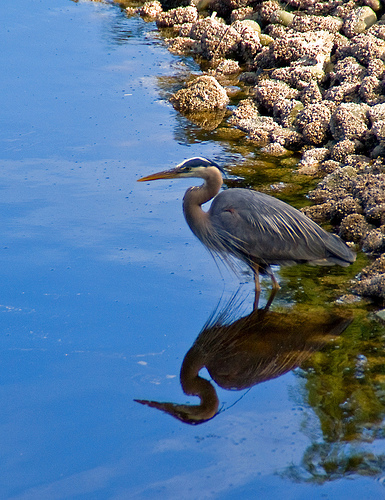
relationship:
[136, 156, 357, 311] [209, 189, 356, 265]
aquatic bird has body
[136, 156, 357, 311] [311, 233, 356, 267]
aquatic bird has tail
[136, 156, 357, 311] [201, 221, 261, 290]
aquatic bird has feathers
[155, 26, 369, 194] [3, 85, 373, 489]
rocks near water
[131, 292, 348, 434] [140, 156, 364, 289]
reflection of crane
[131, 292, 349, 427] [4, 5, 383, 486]
reflection in water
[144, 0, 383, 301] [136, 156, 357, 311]
rocks behind aquatic bird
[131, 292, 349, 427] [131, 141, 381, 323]
reflection of crane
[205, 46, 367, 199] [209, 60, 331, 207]
coral with mold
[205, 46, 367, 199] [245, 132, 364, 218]
coral with algae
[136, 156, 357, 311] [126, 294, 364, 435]
aquatic bird and its reflection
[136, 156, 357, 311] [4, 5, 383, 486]
aquatic bird on banks of water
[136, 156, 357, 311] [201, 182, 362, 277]
aquatic bird with feathers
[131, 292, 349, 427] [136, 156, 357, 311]
reflection of aquatic bird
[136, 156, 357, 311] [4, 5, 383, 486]
aquatic bird on water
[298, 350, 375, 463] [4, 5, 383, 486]
moss reflected in water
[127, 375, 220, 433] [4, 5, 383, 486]
bird's head reflected in water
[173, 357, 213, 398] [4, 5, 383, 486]
neck reflected in water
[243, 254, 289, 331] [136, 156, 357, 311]
long legs of aquatic bird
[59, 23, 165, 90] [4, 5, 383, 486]
ripples on surface of water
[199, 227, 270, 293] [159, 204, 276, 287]
feathers sticking out from birds' chest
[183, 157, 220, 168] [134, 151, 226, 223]
black stripe on birds head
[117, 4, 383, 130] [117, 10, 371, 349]
rocks on shore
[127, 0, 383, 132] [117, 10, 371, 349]
growth on shore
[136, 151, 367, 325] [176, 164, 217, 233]
aquatic bird with long neck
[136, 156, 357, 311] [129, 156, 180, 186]
aquatic bird with beak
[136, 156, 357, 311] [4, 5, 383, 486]
aquatic bird standing in water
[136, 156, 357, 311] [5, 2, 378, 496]
aquatic bird wading out into lake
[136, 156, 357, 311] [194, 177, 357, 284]
aquatic bird with long feathers